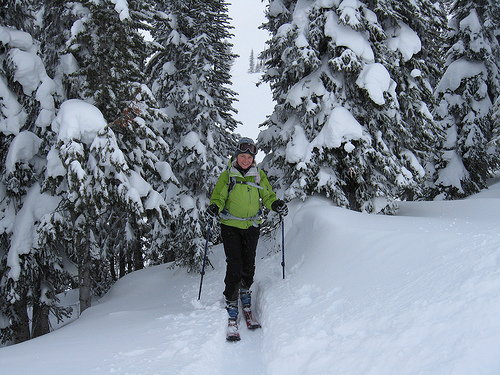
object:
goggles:
[237, 143, 260, 153]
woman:
[207, 138, 289, 312]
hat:
[235, 138, 256, 157]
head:
[235, 137, 255, 168]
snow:
[13, 47, 35, 76]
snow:
[7, 211, 34, 238]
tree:
[280, 4, 497, 204]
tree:
[21, 25, 160, 279]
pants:
[220, 222, 260, 301]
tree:
[242, 47, 255, 74]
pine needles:
[386, 102, 431, 153]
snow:
[261, 11, 500, 209]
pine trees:
[0, 0, 232, 279]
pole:
[198, 219, 212, 300]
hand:
[204, 205, 218, 221]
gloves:
[272, 199, 288, 217]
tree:
[248, 49, 256, 76]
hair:
[235, 137, 256, 156]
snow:
[323, 202, 500, 231]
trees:
[0, 0, 498, 344]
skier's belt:
[222, 209, 262, 220]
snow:
[0, 232, 500, 375]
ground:
[326, 235, 428, 315]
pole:
[279, 215, 287, 279]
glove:
[203, 203, 219, 217]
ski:
[225, 301, 242, 341]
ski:
[242, 306, 262, 329]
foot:
[241, 291, 252, 307]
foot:
[225, 299, 239, 318]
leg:
[223, 230, 241, 302]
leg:
[239, 229, 260, 291]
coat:
[214, 164, 279, 228]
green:
[230, 195, 250, 210]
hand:
[271, 199, 289, 216]